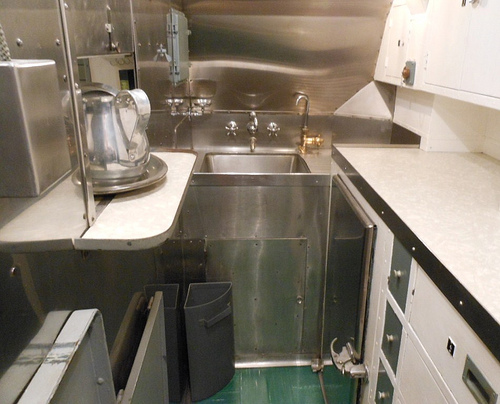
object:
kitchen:
[0, 0, 499, 404]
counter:
[331, 144, 498, 404]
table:
[451, 221, 497, 279]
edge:
[203, 172, 305, 177]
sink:
[196, 153, 311, 178]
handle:
[199, 301, 232, 327]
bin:
[183, 282, 236, 401]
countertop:
[372, 156, 489, 188]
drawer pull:
[394, 269, 402, 278]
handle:
[328, 336, 367, 379]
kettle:
[60, 82, 151, 185]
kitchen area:
[1, 0, 498, 402]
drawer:
[386, 236, 414, 315]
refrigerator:
[320, 174, 378, 403]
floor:
[231, 364, 354, 403]